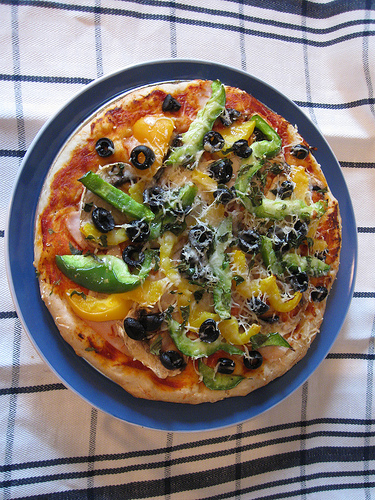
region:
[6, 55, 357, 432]
pizza on a blue plate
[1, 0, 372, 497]
pizza on a blue and white cloth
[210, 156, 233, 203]
olives on the pizza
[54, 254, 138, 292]
green pepper on the pizza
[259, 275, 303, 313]
yellow pepper on the pizza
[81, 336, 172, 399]
tomato sauce on the crust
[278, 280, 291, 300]
white cheese on the pizza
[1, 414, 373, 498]
plaid pattern on the table cloth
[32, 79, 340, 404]
th pizza is round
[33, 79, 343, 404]
the pizza is not cut into pieces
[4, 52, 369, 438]
a pizza on a blue dish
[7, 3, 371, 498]
a dish on tablecloth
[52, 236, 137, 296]
slice of pepper on pizza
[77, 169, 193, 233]
slices of green pepper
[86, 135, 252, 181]
slices of green olives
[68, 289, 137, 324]
yellow pepper on pizza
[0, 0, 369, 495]
a napkin is squared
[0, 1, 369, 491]
blue striped lines on tablecloth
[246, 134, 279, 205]
green pepper on pizza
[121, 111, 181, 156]
yellow pepper on pizza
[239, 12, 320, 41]
black lines on the table cloth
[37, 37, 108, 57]
white table cloth on the table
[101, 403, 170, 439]
edge of blue plate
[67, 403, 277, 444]
blue plate on the table cloth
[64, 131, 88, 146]
brown edge of pizza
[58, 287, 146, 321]
slice of yellow pepper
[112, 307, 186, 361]
pieces of black olives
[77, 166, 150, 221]
green pepper on pizza pie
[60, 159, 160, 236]
slice of button mushroom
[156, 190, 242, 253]
melted cheese on pizza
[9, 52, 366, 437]
Pizza on a blue plate.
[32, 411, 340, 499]
Table cloth under the plate.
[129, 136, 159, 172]
Anchovie on a pizza.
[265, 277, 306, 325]
Pepper on the pizza.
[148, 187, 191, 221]
Cheese sprinkled on a pizza.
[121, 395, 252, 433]
Blue painted plate exterior.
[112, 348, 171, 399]
Crust of the small pizza.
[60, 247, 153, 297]
Green pepper on the pizza.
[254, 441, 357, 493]
Lines on the tablecloth.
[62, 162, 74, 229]
Tomato Sauce on the pizza.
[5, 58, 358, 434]
Pizza sitting on blue plate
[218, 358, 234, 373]
Black sliced olive on top of pizza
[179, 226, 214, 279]
Mozzarella cheese melted on pizza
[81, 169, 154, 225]
Sliced green pepper on pizza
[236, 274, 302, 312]
Sliced yellow pepper on pizza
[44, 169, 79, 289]
Tomato sauce on top of pizza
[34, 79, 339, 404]
Many toppings on top of pizza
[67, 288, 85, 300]
Fresh basil sprinkled on pizza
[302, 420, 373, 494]
Blue stripes on tablecloth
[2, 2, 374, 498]
Blue and white tablecloth under pizza